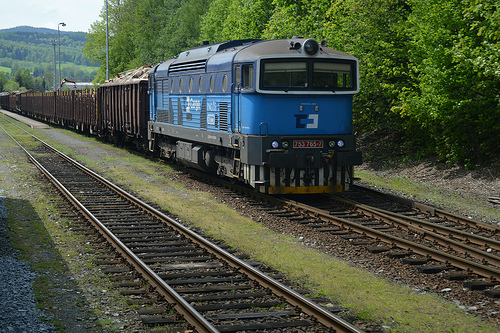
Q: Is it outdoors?
A: Yes, it is outdoors.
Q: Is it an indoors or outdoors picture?
A: It is outdoors.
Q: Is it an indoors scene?
A: No, it is outdoors.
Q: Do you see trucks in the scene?
A: No, there are no trucks.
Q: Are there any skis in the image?
A: No, there are no skis.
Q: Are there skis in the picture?
A: No, there are no skis.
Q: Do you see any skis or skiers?
A: No, there are no skis or skiers.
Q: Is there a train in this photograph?
A: Yes, there is a train.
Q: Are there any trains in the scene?
A: Yes, there is a train.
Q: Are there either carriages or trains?
A: Yes, there is a train.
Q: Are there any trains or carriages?
A: Yes, there is a train.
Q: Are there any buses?
A: No, there are no buses.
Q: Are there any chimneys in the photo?
A: No, there are no chimneys.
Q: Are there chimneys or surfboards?
A: No, there are no chimneys or surfboards.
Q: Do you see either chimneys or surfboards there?
A: No, there are no chimneys or surfboards.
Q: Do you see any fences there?
A: No, there are no fences.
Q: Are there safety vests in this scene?
A: No, there are no safety vests.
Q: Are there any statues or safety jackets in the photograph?
A: No, there are no safety jackets or statues.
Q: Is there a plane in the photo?
A: No, there are no airplanes.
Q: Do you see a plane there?
A: No, there are no airplanes.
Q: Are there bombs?
A: No, there are no bombs.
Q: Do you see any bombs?
A: No, there are no bombs.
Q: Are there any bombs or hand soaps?
A: No, there are no bombs or hand soaps.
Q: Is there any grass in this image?
A: Yes, there is grass.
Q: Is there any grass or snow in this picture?
A: Yes, there is grass.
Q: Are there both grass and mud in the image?
A: No, there is grass but no mud.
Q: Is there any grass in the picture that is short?
A: Yes, there is short grass.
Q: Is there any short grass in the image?
A: Yes, there is short grass.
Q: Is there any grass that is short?
A: Yes, there is grass that is short.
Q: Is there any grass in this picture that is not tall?
A: Yes, there is short grass.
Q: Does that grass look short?
A: Yes, the grass is short.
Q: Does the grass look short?
A: Yes, the grass is short.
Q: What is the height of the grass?
A: The grass is short.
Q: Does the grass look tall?
A: No, the grass is short.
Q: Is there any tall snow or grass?
A: No, there is grass but it is short.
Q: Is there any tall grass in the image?
A: No, there is grass but it is short.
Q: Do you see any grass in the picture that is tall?
A: No, there is grass but it is short.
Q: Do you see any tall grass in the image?
A: No, there is grass but it is short.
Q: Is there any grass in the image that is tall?
A: No, there is grass but it is short.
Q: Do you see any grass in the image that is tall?
A: No, there is grass but it is short.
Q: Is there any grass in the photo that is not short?
A: No, there is grass but it is short.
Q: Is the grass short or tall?
A: The grass is short.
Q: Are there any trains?
A: Yes, there is a train.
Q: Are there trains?
A: Yes, there is a train.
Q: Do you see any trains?
A: Yes, there is a train.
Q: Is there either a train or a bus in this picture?
A: Yes, there is a train.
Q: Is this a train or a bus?
A: This is a train.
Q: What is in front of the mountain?
A: The train is in front of the mountain.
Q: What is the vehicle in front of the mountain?
A: The vehicle is a train.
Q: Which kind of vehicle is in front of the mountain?
A: The vehicle is a train.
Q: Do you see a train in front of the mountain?
A: Yes, there is a train in front of the mountain.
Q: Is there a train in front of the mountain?
A: Yes, there is a train in front of the mountain.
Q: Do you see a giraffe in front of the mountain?
A: No, there is a train in front of the mountain.